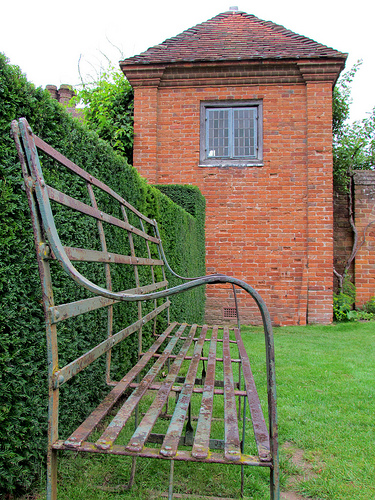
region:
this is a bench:
[70, 197, 234, 407]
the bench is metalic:
[116, 245, 216, 429]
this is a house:
[197, 78, 344, 345]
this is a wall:
[228, 193, 284, 253]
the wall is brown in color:
[232, 192, 273, 237]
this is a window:
[198, 106, 267, 153]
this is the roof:
[219, 16, 274, 47]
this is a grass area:
[303, 325, 373, 430]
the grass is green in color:
[305, 357, 368, 464]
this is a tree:
[83, 80, 114, 126]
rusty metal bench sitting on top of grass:
[9, 116, 282, 498]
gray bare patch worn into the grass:
[279, 438, 315, 498]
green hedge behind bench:
[0, 48, 208, 498]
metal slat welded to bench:
[234, 325, 272, 461]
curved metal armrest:
[62, 256, 273, 328]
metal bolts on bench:
[57, 374, 65, 383]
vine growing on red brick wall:
[334, 168, 364, 322]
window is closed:
[204, 107, 257, 160]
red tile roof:
[116, 4, 349, 61]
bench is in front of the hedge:
[10, 117, 278, 498]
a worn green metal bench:
[6, 107, 280, 498]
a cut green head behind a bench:
[1, 52, 206, 499]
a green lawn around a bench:
[30, 318, 372, 497]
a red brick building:
[120, 5, 346, 324]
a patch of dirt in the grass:
[278, 438, 316, 498]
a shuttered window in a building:
[199, 102, 263, 164]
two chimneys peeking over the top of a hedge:
[45, 79, 78, 107]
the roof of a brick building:
[114, 5, 350, 66]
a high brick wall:
[334, 165, 373, 306]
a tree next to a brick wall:
[332, 166, 367, 295]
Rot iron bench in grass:
[13, 113, 303, 498]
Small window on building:
[195, 86, 283, 190]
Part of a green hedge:
[3, 60, 87, 143]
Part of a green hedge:
[64, 111, 109, 164]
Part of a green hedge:
[99, 132, 142, 191]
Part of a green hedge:
[128, 170, 178, 226]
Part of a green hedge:
[160, 169, 205, 259]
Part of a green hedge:
[12, 309, 43, 432]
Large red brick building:
[102, 6, 357, 361]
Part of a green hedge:
[64, 373, 127, 405]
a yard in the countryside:
[15, 2, 360, 444]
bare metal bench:
[8, 112, 286, 489]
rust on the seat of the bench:
[171, 354, 246, 389]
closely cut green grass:
[290, 331, 365, 425]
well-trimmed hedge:
[147, 180, 209, 225]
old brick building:
[121, 5, 339, 147]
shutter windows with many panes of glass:
[199, 99, 260, 161]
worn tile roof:
[120, 10, 342, 63]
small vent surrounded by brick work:
[219, 302, 236, 317]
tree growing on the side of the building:
[330, 117, 366, 317]